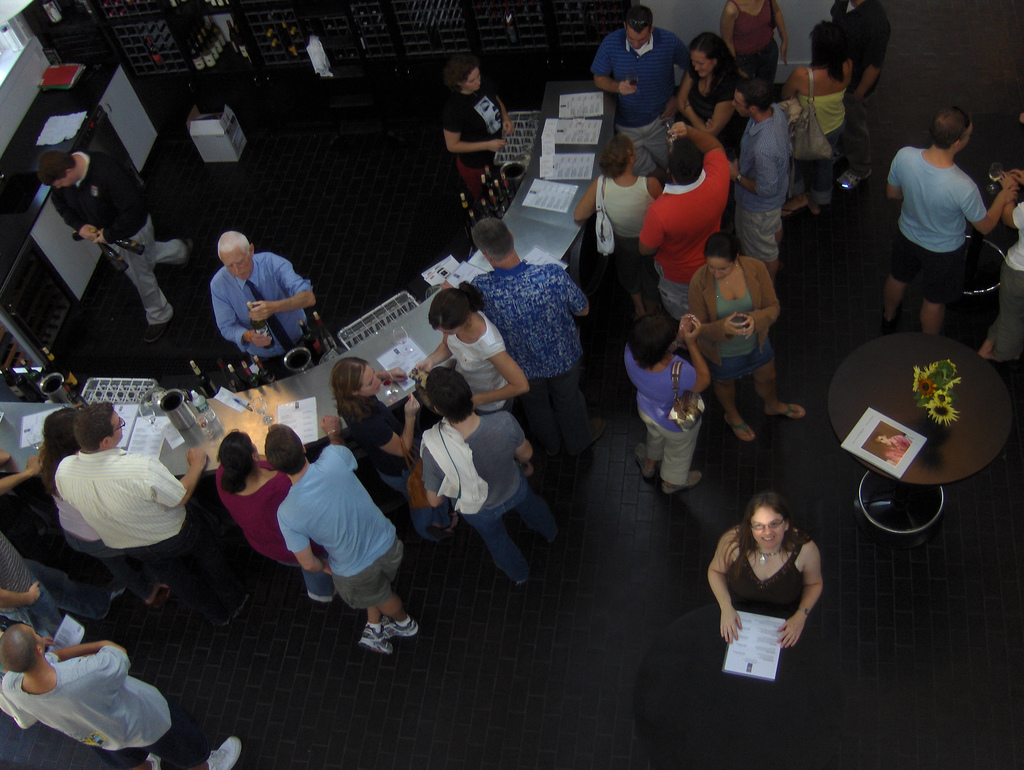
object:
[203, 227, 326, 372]
man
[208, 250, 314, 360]
shirt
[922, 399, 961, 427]
sunflowers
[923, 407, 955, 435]
vase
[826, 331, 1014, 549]
table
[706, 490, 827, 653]
woman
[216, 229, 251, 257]
hair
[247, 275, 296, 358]
tie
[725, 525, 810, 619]
tank top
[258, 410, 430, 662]
man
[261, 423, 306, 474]
top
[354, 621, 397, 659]
sneaker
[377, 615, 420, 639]
sneaker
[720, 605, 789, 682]
menu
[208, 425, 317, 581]
woman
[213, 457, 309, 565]
shirt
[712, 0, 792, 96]
woman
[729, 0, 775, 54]
shirt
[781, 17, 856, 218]
woman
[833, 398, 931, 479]
book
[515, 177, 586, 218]
menu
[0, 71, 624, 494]
bar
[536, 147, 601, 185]
menu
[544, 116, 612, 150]
menu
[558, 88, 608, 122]
menu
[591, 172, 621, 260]
purse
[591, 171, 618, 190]
woman's shoulder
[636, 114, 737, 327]
man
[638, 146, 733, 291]
shirt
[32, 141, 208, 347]
man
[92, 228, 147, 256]
bottle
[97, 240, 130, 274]
bottle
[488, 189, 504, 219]
bottle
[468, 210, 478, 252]
bottle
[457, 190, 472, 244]
bottle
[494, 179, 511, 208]
bottle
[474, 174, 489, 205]
bottle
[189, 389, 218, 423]
water bottle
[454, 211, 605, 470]
man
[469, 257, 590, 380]
shirt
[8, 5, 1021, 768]
floor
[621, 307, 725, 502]
woman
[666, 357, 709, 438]
purse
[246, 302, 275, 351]
bottle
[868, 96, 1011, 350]
man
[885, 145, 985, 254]
shirt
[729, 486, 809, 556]
hair